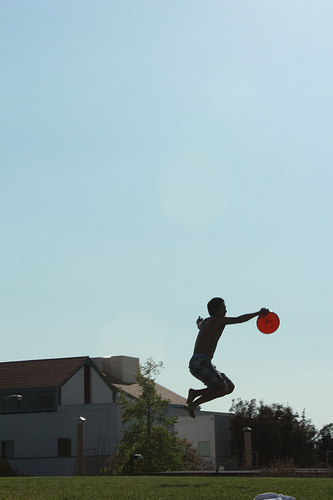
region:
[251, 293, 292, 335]
the frisbee is orange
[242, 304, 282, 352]
the frisbee is orange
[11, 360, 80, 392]
the roof is brown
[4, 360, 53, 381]
the roof is brown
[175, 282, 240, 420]
this is a person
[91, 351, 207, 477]
this is a tree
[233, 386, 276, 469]
this is a tree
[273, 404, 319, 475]
this is a tree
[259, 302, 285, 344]
this is a red Frisbee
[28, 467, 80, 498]
this is grass at the field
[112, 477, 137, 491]
this is grass at the field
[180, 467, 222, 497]
this is grass at the field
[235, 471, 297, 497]
this is grass at the field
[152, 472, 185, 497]
this is grass at the field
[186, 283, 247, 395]
boy jumps in air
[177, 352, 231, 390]
boy is wearing shorts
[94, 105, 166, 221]
sky is bright blue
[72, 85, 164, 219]
no clouds in sky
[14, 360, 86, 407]
brown roof on building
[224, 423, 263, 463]
brown pole behind boy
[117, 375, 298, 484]
green trees behind boy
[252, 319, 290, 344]
boy holds orange frisbee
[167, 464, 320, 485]
grey rail in distance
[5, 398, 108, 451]
white wall on building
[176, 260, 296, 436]
man caught the frisbee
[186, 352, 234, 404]
the man is wearing shorts